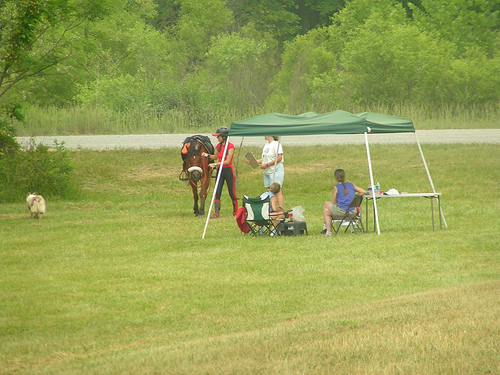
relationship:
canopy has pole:
[257, 117, 363, 127] [366, 132, 370, 154]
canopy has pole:
[257, 117, 363, 127] [413, 133, 419, 143]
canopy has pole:
[257, 117, 363, 127] [278, 137, 283, 143]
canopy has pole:
[257, 117, 363, 127] [227, 138, 229, 149]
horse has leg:
[186, 133, 205, 212] [201, 187, 206, 198]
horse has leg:
[186, 133, 205, 212] [193, 187, 198, 199]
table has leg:
[407, 191, 441, 196] [437, 196, 443, 227]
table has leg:
[407, 191, 441, 196] [430, 198, 434, 208]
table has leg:
[407, 191, 441, 196] [366, 200, 369, 208]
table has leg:
[407, 191, 441, 196] [372, 219, 376, 232]